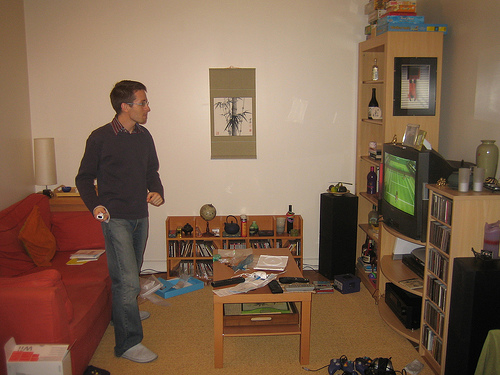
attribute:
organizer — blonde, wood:
[161, 213, 305, 288]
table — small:
[204, 228, 326, 369]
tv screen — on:
[380, 135, 425, 221]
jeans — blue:
[94, 210, 159, 355]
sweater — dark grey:
[78, 122, 159, 209]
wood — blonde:
[401, 163, 468, 345]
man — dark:
[74, 78, 164, 360]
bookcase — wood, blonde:
[338, 36, 438, 301]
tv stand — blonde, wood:
[371, 215, 431, 343]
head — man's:
[111, 65, 206, 148]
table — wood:
[205, 249, 309, 359]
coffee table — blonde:
[213, 246, 318, 368]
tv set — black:
[372, 152, 424, 237]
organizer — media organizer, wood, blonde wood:
[419, 177, 496, 374]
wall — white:
[24, 0, 367, 271]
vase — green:
[474, 134, 498, 190]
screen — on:
[380, 149, 418, 217]